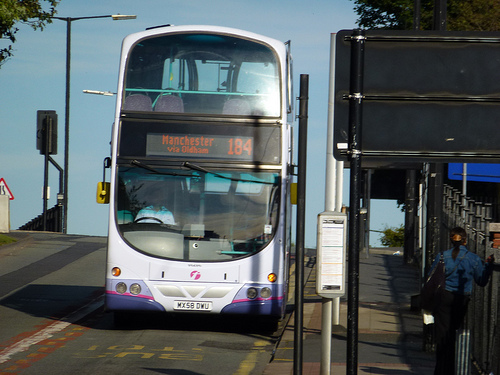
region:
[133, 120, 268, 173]
digital sign on bus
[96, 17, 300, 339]
large white and purple bus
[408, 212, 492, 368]
woman in denim jacket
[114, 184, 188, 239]
driver of large bus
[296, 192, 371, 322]
metal bus route sign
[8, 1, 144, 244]
tall metal lamp post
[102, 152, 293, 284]
window of large bus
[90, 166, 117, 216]
yellow side mirror of bus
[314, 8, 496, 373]
woman standing at bus stop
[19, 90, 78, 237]
tall black traffic light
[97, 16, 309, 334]
A bus is parked next to a sidewalk.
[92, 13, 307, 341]
The colors of a bus are white, blue, black, orange, yellow, and red.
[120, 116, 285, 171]
A destination indicator is at the front of a bus.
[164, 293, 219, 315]
The color of a license plate is white and black.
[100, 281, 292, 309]
A red strip is running across the bottom front of a bus.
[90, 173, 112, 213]
The color of an outside mirror is yellow.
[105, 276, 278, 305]
Headlights of a bus are just above a red strip.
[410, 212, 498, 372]
A person is walking down a sidewalk.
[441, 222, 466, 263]
A person is wearing a ponytail.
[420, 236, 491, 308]
A person is wearing a blue shirt.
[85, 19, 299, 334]
a modern looking double decker bus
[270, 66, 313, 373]
a black post beside the road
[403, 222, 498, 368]
a man on the sidewalk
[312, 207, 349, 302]
bus schedule posted on a sign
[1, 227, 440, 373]
road with a downhill slope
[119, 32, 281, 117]
upper window on the bus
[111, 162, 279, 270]
windshield on the bus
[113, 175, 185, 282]
bus driver on the right of the bus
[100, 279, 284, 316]
purple area of front of bus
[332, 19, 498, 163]
back of a sign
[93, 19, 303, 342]
a double decker bus color white and purple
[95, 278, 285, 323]
bumper of bus is purple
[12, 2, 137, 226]
a pole with two lights on the top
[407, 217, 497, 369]
woman has a purse on left shoulder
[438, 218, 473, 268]
woman combs with a pony tail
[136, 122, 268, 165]
letters in middle of the bus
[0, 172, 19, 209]
a sign with red border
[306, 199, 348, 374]
the schedule of a bus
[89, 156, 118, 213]
mirror of bus is yellow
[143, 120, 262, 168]
letters of bus are orange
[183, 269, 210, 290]
small red and white circle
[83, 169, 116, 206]
yellow mirror on side of bus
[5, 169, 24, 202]
portion of red and white sign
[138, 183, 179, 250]
bus driver in position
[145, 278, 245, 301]
gray and white sign on front of bus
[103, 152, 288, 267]
large window on the bus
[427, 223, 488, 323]
person walking on the sidewalk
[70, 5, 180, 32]
tall silver and black street light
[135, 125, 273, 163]
orange words on front of building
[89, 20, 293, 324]
tall white passenger bus